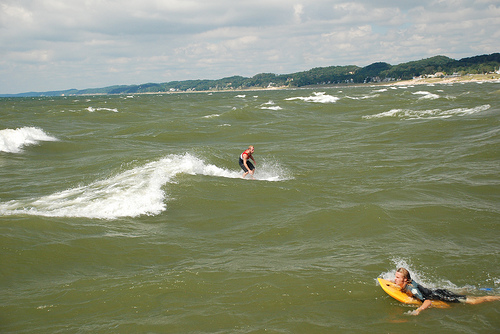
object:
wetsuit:
[404, 279, 467, 307]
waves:
[359, 103, 491, 122]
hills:
[347, 61, 399, 86]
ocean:
[0, 79, 499, 333]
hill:
[273, 64, 364, 87]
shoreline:
[0, 78, 500, 100]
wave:
[0, 147, 295, 221]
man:
[389, 266, 500, 318]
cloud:
[0, 0, 499, 75]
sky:
[0, 1, 500, 96]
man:
[236, 142, 259, 181]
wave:
[0, 124, 59, 157]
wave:
[284, 90, 344, 106]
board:
[371, 275, 450, 310]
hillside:
[380, 55, 465, 80]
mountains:
[449, 52, 500, 76]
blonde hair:
[394, 266, 414, 282]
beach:
[0, 70, 498, 99]